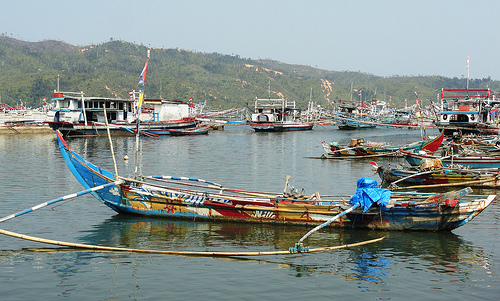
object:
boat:
[43, 114, 204, 138]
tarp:
[347, 177, 388, 208]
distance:
[6, 42, 498, 133]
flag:
[126, 49, 150, 104]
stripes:
[120, 183, 209, 208]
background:
[0, 1, 499, 300]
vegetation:
[0, 35, 499, 109]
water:
[1, 108, 493, 296]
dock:
[12, 105, 54, 133]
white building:
[138, 96, 194, 123]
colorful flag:
[129, 47, 151, 182]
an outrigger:
[343, 177, 390, 211]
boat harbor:
[42, 89, 199, 130]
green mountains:
[0, 35, 382, 103]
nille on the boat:
[243, 209, 279, 222]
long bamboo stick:
[0, 226, 385, 258]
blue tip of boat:
[55, 131, 497, 232]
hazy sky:
[0, 4, 495, 70]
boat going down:
[55, 128, 493, 259]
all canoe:
[322, 137, 407, 158]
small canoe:
[117, 122, 199, 135]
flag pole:
[128, 48, 153, 190]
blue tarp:
[346, 177, 392, 212]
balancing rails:
[0, 170, 223, 257]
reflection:
[67, 205, 157, 280]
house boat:
[125, 95, 192, 124]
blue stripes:
[74, 188, 92, 198]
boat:
[166, 124, 213, 136]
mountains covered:
[0, 35, 498, 112]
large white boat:
[429, 91, 494, 125]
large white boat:
[333, 99, 381, 129]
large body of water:
[2, 121, 495, 298]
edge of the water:
[2, 122, 58, 137]